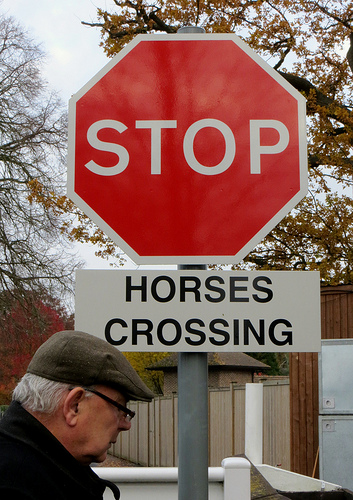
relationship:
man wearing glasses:
[0, 329, 156, 500] [68, 376, 152, 440]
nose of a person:
[119, 415, 130, 432] [2, 329, 135, 496]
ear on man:
[61, 385, 87, 426] [0, 329, 156, 500]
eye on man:
[111, 398, 126, 417] [0, 329, 156, 500]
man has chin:
[0, 329, 156, 500] [85, 438, 121, 480]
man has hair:
[0, 329, 156, 500] [21, 358, 90, 412]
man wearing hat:
[2, 329, 142, 497] [25, 327, 153, 402]